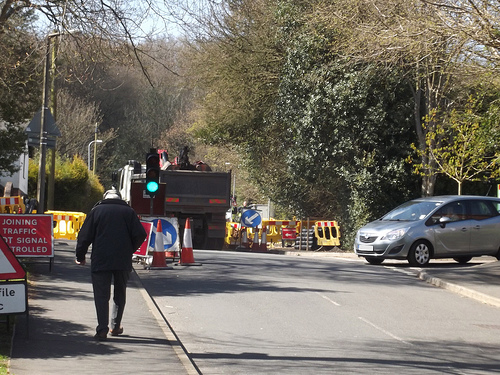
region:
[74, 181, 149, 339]
A person walking on the sidewalk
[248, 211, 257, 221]
Part of the sign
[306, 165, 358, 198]
Part of the green tree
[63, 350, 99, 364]
Part of the sidewalk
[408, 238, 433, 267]
The front tire of the car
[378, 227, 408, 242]
The headlight of the car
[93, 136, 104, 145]
Part of the streetlight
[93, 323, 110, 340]
The left foot of the person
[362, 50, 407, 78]
Leaves in a tree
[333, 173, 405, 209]
Leaves in a tree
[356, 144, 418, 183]
Leaves in a tree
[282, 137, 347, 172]
Leaves in a tree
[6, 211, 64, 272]
White and red traffic sign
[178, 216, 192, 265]
White and red traffic cone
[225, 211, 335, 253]
Yellow and red traffic things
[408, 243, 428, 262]
Black tire on a car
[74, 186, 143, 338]
Old man walking on the sidewalk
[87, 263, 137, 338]
Man wearing black pants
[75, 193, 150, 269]
Man wearing a black jacket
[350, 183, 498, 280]
Grey car on the road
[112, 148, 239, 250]
Dump truck parked on the road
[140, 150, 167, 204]
Green traffic light is illuminated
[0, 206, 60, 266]
Red traffic sign indicating signal ahead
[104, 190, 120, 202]
Old man with grey hair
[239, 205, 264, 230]
Sign is white and blue with a white arrow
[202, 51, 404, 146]
trees next to the street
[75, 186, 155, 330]
a man walking down the street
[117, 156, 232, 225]
a truck driving down the street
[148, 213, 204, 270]
orange traffic cones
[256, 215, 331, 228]
a red gate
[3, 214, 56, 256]
a red street sign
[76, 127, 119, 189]
a lamp post next to the street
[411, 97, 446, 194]
the trunk of the tree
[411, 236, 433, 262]
tire on the car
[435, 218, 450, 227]
side view on the car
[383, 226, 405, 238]
headlight on the car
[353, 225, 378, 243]
grill on the car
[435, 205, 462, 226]
window on the car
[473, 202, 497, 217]
window on the car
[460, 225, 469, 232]
door handle on the car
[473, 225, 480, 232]
door handle on the car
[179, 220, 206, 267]
traffic cone in the street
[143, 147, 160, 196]
traffic light on a pole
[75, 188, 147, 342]
a man wearing a black jacket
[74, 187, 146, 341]
a man wearing dark pants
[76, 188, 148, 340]
a man in a hat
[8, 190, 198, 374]
a man walking on a sidewalk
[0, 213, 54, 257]
a red and white sign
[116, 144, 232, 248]
a large truck being driven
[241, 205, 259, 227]
a sign with a white arrow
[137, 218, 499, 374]
traffic cones on the street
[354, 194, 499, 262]
a silver car is being driven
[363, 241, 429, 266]
front tires are black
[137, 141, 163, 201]
A traffic light is green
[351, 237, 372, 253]
A white license plate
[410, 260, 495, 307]
The curb of a sidewalk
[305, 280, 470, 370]
White lines on the road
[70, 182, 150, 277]
Man wearing a black jacket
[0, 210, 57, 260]
White writing on red sign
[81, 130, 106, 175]
The top of a street light